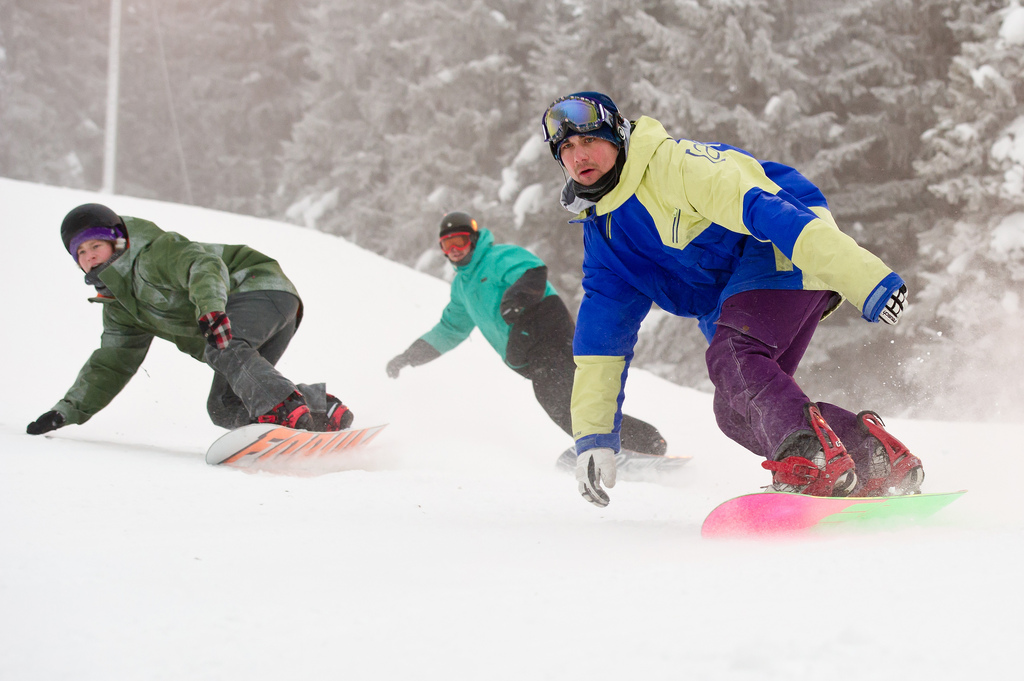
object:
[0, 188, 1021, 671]
snow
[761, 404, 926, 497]
snowboard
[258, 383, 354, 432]
snowboard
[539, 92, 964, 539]
skier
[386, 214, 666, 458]
person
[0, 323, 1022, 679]
ground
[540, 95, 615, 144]
goggles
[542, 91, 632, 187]
head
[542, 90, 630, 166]
helmet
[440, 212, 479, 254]
helmet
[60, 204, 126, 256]
helmet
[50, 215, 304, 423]
coat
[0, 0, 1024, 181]
evergreens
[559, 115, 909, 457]
jacket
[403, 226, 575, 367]
jacket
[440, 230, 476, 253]
goggles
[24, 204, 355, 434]
snowboarder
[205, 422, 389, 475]
snowboard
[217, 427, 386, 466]
letters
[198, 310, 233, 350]
glove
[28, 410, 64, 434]
glove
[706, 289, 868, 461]
ski pants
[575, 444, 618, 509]
glove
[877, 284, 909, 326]
glove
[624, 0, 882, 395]
pine trees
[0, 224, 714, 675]
slope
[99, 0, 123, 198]
pole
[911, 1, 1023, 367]
trees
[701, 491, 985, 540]
snowboard